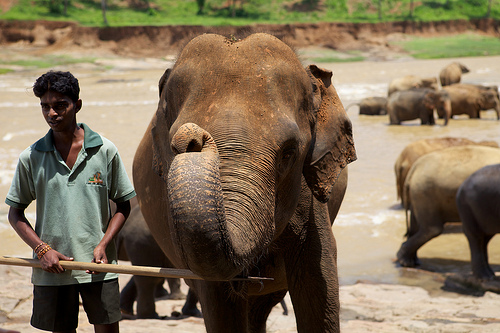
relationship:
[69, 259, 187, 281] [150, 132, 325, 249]
poll in elephant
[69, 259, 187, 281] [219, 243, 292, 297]
poll in mouth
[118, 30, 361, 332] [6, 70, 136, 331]
elephant next to man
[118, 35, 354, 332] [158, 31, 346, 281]
elephant has dirt on head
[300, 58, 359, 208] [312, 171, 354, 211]
elephant ear covered by mud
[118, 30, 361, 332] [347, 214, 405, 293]
elephant in water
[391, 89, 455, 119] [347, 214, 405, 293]
elephant in water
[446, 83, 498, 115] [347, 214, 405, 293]
elephant in water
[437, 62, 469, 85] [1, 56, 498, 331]
elephant in water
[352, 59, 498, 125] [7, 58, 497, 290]
elephants in water